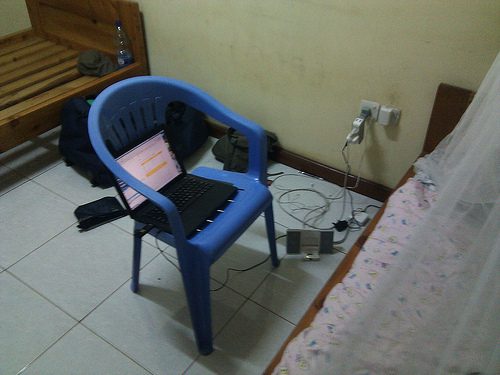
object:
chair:
[88, 74, 283, 358]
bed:
[267, 84, 497, 372]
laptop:
[107, 123, 240, 240]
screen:
[114, 130, 183, 211]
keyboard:
[144, 176, 213, 223]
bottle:
[112, 18, 134, 69]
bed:
[0, 2, 151, 158]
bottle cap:
[115, 20, 122, 26]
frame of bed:
[266, 84, 473, 374]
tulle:
[272, 52, 499, 372]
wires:
[275, 142, 356, 231]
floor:
[1, 127, 388, 373]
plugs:
[357, 107, 370, 121]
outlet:
[359, 99, 380, 122]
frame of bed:
[1, 1, 149, 150]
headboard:
[423, 84, 472, 161]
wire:
[155, 231, 293, 292]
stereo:
[286, 229, 334, 261]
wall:
[138, 4, 500, 186]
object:
[72, 196, 129, 228]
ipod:
[354, 210, 370, 226]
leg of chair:
[177, 250, 217, 355]